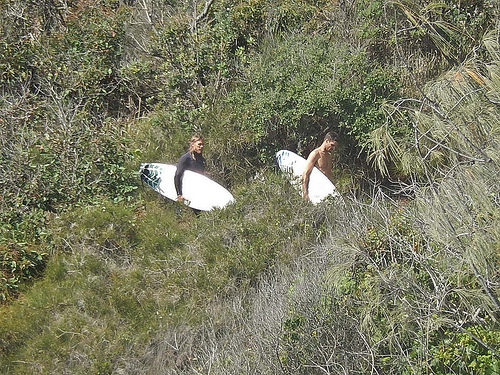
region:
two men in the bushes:
[118, 105, 424, 271]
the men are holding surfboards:
[120, 80, 402, 282]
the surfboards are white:
[113, 121, 375, 257]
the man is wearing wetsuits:
[144, 95, 229, 238]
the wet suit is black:
[175, 137, 232, 236]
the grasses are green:
[199, 50, 256, 137]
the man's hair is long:
[179, 121, 220, 163]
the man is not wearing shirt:
[296, 147, 373, 226]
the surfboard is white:
[260, 135, 357, 222]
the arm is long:
[287, 144, 316, 223]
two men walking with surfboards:
[127, 112, 354, 232]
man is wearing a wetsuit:
[166, 120, 208, 210]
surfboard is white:
[134, 162, 242, 215]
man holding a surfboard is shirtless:
[272, 125, 360, 222]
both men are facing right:
[116, 117, 359, 244]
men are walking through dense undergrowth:
[6, 6, 491, 373]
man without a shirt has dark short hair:
[292, 127, 341, 204]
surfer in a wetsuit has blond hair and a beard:
[164, 130, 216, 218]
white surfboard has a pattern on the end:
[132, 155, 244, 217]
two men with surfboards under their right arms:
[128, 117, 365, 234]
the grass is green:
[84, 239, 224, 329]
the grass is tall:
[90, 220, 215, 350]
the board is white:
[145, 152, 247, 227]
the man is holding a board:
[119, 94, 266, 251]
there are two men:
[148, 100, 382, 246]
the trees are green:
[42, 27, 109, 161]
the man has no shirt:
[263, 113, 364, 235]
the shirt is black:
[169, 130, 211, 206]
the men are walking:
[147, 105, 373, 237]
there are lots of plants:
[26, 10, 468, 355]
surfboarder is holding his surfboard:
[135, 132, 247, 232]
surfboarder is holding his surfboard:
[266, 107, 373, 252]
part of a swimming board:
[311, 180, 333, 195]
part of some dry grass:
[277, 270, 339, 331]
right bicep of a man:
[303, 152, 313, 172]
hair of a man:
[188, 132, 202, 140]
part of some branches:
[3, 102, 68, 155]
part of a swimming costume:
[186, 156, 198, 166]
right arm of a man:
[298, 178, 310, 193]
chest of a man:
[318, 154, 333, 169]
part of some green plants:
[427, 319, 469, 364]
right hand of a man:
[171, 191, 186, 207]